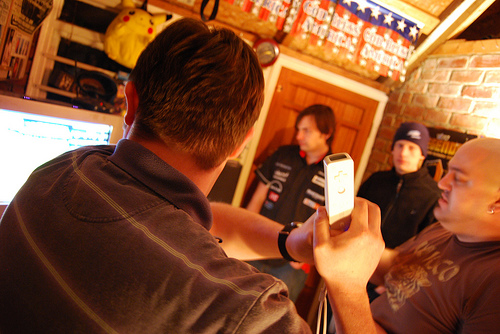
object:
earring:
[487, 210, 494, 214]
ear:
[490, 191, 500, 214]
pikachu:
[103, 0, 173, 70]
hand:
[312, 196, 386, 287]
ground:
[373, 160, 385, 190]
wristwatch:
[277, 225, 300, 258]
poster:
[425, 134, 475, 158]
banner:
[214, 0, 427, 84]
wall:
[80, 0, 499, 82]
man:
[0, 17, 385, 334]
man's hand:
[312, 196, 386, 334]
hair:
[295, 103, 336, 145]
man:
[243, 104, 336, 302]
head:
[123, 17, 261, 195]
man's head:
[433, 137, 500, 242]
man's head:
[295, 104, 338, 152]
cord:
[313, 296, 333, 334]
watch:
[278, 222, 299, 262]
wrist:
[273, 227, 300, 262]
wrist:
[328, 276, 370, 308]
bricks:
[382, 54, 500, 118]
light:
[481, 113, 500, 138]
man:
[355, 122, 443, 250]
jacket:
[355, 166, 443, 250]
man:
[289, 137, 500, 334]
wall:
[360, 38, 500, 184]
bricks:
[364, 117, 404, 175]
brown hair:
[127, 17, 264, 172]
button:
[334, 170, 349, 195]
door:
[237, 66, 379, 207]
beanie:
[392, 121, 429, 157]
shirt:
[0, 137, 310, 333]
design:
[384, 240, 460, 314]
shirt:
[367, 220, 500, 334]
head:
[393, 121, 426, 173]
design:
[407, 130, 422, 140]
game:
[323, 152, 355, 231]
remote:
[323, 152, 353, 232]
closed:
[239, 65, 379, 210]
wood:
[239, 66, 379, 209]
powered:
[0, 108, 113, 206]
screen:
[0, 107, 112, 208]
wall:
[55, 56, 116, 78]